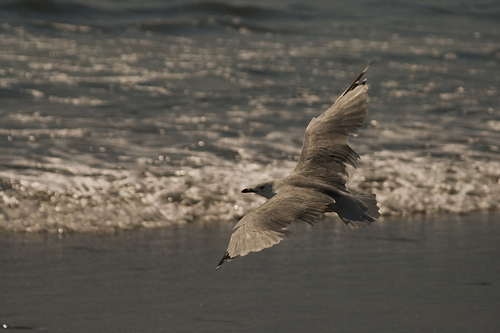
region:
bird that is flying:
[207, 59, 417, 278]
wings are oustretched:
[217, 68, 383, 270]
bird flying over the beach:
[1, 4, 493, 330]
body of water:
[2, 1, 490, 234]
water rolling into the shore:
[3, 167, 499, 224]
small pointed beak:
[233, 181, 256, 198]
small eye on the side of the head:
[257, 184, 267, 192]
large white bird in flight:
[185, 74, 424, 271]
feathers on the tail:
[335, 182, 400, 241]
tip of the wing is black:
[212, 250, 232, 271]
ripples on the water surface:
[356, 38, 468, 133]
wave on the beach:
[0, 143, 494, 275]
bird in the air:
[208, 63, 413, 301]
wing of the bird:
[297, 58, 388, 178]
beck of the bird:
[240, 175, 257, 200]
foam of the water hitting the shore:
[0, 158, 469, 243]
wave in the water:
[6, 58, 258, 130]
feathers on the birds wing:
[333, 95, 375, 191]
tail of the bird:
[336, 180, 386, 233]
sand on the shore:
[85, 207, 494, 332]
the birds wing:
[229, 217, 311, 259]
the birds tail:
[335, 194, 386, 236]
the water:
[27, 148, 182, 215]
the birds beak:
[238, 183, 255, 198]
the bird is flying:
[205, 75, 405, 269]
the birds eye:
[257, 182, 268, 193]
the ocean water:
[65, 89, 220, 169]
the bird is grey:
[221, 70, 416, 270]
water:
[392, 155, 482, 204]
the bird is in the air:
[202, 66, 409, 271]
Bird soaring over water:
[220, 62, 405, 284]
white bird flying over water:
[223, 95, 375, 261]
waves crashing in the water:
[61, 122, 178, 256]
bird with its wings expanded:
[193, 67, 378, 284]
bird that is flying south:
[190, 73, 379, 282]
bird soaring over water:
[190, 75, 370, 245]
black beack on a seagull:
[239, 181, 254, 197]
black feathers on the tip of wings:
[330, 61, 375, 109]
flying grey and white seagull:
[194, 42, 399, 267]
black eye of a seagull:
[259, 181, 268, 196]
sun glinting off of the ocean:
[100, 95, 226, 181]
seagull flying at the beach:
[182, 52, 415, 300]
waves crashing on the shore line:
[32, 150, 144, 235]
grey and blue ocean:
[30, 23, 302, 103]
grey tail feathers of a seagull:
[319, 178, 386, 239]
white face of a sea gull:
[250, 174, 275, 205]